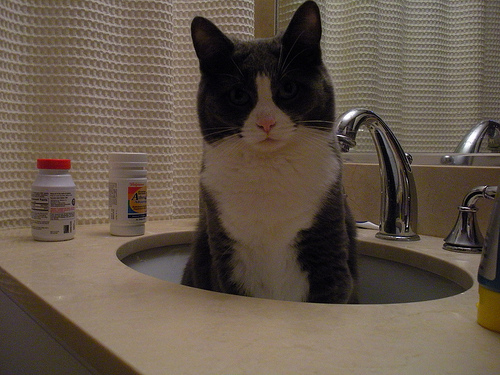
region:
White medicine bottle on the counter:
[26, 151, 80, 246]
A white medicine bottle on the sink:
[101, 146, 149, 240]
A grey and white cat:
[183, 2, 363, 321]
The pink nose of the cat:
[251, 115, 280, 132]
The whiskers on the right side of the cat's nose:
[284, 118, 366, 173]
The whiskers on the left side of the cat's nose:
[179, 123, 268, 168]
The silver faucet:
[333, 93, 433, 240]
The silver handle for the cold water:
[438, 179, 498, 256]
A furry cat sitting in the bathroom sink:
[116, 2, 475, 329]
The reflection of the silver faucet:
[433, 106, 499, 163]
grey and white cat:
[161, 1, 341, 301]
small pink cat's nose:
[242, 112, 291, 144]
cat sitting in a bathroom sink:
[153, 0, 453, 323]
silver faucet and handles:
[325, 96, 496, 269]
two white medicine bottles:
[10, 136, 164, 266]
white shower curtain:
[17, 14, 190, 114]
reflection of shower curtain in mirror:
[367, 20, 469, 87]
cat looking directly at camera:
[180, 2, 351, 293]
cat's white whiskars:
[194, 113, 366, 165]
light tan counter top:
[72, 257, 177, 355]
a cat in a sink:
[180, 1, 375, 311]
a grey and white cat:
[169, 0, 383, 305]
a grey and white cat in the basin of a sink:
[177, 0, 394, 285]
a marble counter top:
[169, 309, 427, 373]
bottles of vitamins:
[19, 133, 163, 260]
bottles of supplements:
[15, 121, 161, 253]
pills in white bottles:
[8, 134, 166, 239]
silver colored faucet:
[338, 98, 440, 253]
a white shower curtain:
[5, 4, 189, 153]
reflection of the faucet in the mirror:
[432, 100, 497, 173]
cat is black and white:
[178, 0, 361, 305]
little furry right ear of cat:
[190, 16, 233, 76]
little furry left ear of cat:
[279, 0, 324, 57]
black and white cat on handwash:
[179, 0, 361, 298]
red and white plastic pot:
[29, 152, 77, 244]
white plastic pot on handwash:
[110, 149, 150, 231]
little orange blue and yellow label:
[125, 180, 147, 220]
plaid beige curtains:
[3, 0, 252, 222]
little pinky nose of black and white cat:
[255, 116, 275, 131]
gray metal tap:
[333, 106, 420, 240]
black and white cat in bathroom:
[12, 1, 485, 357]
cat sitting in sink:
[177, 0, 362, 310]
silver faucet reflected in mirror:
[332, 97, 492, 172]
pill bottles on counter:
[26, 146, 146, 246]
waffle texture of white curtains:
[6, 5, 171, 145]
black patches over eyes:
[190, 65, 330, 115]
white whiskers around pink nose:
[175, 110, 350, 165]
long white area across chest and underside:
[192, 130, 339, 300]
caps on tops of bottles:
[32, 140, 147, 175]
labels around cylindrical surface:
[26, 165, 148, 237]